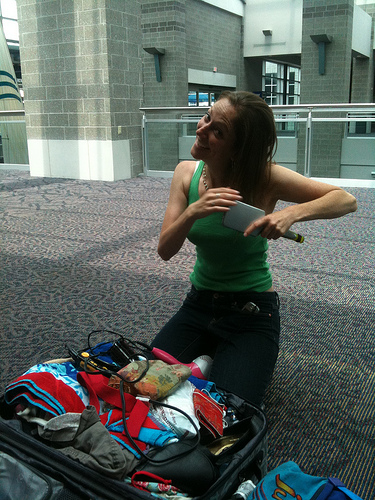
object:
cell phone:
[241, 300, 260, 315]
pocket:
[235, 304, 273, 336]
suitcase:
[1, 343, 268, 496]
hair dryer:
[152, 347, 214, 379]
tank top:
[185, 156, 273, 290]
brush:
[223, 201, 305, 244]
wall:
[184, 3, 241, 86]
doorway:
[187, 84, 235, 105]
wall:
[111, 5, 143, 174]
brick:
[112, 56, 129, 70]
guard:
[144, 118, 374, 178]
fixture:
[309, 31, 332, 75]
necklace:
[199, 166, 213, 193]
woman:
[155, 91, 358, 393]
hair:
[224, 90, 279, 190]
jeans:
[152, 288, 282, 396]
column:
[20, 2, 114, 182]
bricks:
[20, 18, 37, 34]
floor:
[3, 183, 375, 496]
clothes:
[70, 405, 130, 479]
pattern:
[2, 67, 15, 80]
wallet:
[193, 390, 224, 439]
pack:
[252, 459, 359, 500]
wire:
[86, 330, 199, 467]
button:
[212, 291, 220, 300]